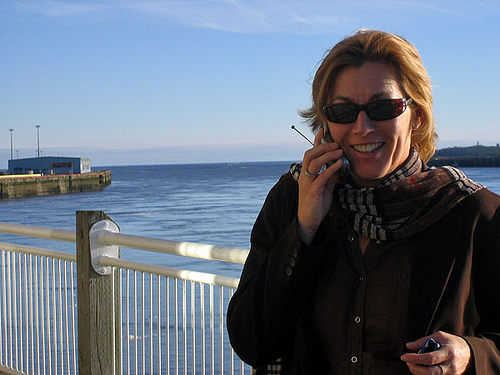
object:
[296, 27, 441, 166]
hair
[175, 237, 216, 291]
sunlight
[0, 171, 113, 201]
pier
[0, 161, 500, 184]
ocean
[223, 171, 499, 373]
sweater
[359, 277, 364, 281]
button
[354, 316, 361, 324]
button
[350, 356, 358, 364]
button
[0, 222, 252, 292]
railing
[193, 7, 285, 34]
cloud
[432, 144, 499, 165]
hills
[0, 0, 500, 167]
sky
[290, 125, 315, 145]
antenna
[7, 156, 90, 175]
building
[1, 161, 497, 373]
water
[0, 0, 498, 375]
picture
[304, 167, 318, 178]
ring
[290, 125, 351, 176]
cell phone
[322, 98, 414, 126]
sunglasses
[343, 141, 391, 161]
smile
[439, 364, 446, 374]
ring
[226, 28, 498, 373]
woman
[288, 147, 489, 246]
scarf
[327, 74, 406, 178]
face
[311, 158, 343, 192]
finger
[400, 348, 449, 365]
finger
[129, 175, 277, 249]
waves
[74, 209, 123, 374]
post